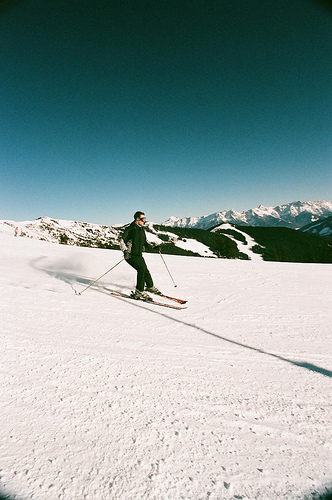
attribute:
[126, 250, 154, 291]
pants — black, padded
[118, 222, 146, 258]
winter jacket — black, white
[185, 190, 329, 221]
mountaintops — grey, rocky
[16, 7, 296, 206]
sky — many shades of blue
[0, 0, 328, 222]
sky — blue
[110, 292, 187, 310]
ski — red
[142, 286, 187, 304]
ski — red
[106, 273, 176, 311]
boots — grey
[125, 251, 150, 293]
pants — black, for skiing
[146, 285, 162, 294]
boot — grey, white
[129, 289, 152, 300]
boot — grey, white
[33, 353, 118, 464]
ground — snow-covered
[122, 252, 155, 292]
pants — black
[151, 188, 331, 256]
mountains —  with snow 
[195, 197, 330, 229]
mountain tops — snowy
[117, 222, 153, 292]
clothes —  for ski